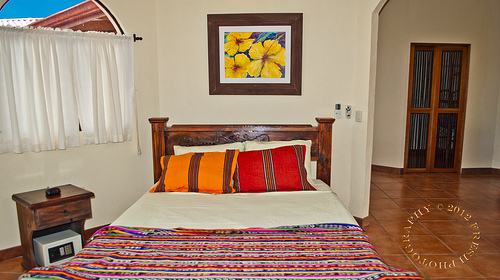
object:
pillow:
[149, 149, 240, 194]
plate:
[147, 117, 335, 187]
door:
[402, 42, 472, 173]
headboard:
[149, 116, 336, 187]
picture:
[219, 25, 292, 84]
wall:
[0, 0, 158, 247]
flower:
[224, 32, 254, 57]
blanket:
[16, 223, 421, 280]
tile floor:
[354, 165, 499, 278]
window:
[0, 0, 128, 139]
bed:
[17, 117, 421, 280]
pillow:
[173, 142, 244, 156]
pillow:
[226, 145, 317, 193]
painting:
[219, 25, 291, 84]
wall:
[156, 8, 207, 108]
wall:
[380, 0, 498, 174]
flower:
[247, 39, 286, 78]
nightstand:
[12, 184, 95, 270]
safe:
[33, 229, 83, 267]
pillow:
[243, 139, 313, 183]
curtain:
[0, 24, 136, 155]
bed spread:
[16, 179, 424, 280]